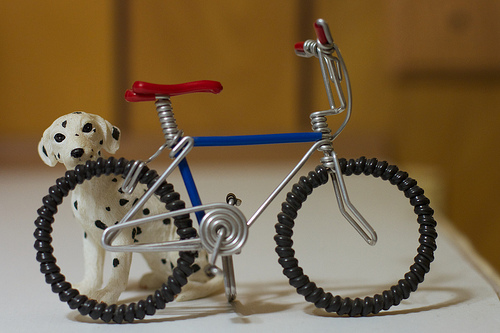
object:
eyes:
[54, 133, 66, 143]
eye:
[82, 123, 93, 133]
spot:
[111, 126, 121, 141]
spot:
[94, 219, 109, 230]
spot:
[119, 198, 130, 206]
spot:
[142, 207, 150, 215]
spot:
[61, 120, 67, 128]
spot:
[72, 200, 79, 210]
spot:
[112, 257, 120, 268]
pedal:
[187, 263, 226, 284]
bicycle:
[27, 18, 438, 326]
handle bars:
[289, 14, 344, 60]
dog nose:
[70, 148, 85, 158]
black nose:
[70, 148, 85, 158]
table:
[0, 160, 493, 333]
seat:
[122, 77, 225, 105]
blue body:
[171, 127, 323, 232]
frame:
[96, 18, 379, 255]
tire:
[274, 152, 439, 317]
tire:
[32, 154, 203, 324]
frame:
[98, 112, 377, 262]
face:
[42, 112, 104, 167]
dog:
[36, 109, 223, 324]